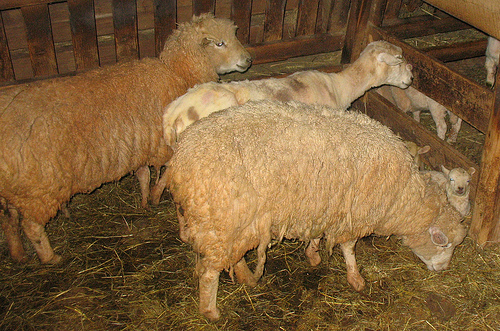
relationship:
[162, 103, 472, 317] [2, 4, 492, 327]
sheep in section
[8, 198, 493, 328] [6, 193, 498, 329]
hay on ground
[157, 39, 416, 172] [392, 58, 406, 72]
lamb has eyes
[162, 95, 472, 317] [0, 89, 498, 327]
sheep eating hay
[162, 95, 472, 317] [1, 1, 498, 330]
sheep in background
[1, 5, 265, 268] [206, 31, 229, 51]
sheep has eye ball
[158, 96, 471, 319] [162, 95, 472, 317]
wool on sheep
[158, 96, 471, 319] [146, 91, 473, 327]
wool on sheep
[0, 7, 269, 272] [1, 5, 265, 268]
wool on sheep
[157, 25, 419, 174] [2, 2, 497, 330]
lamb in barn